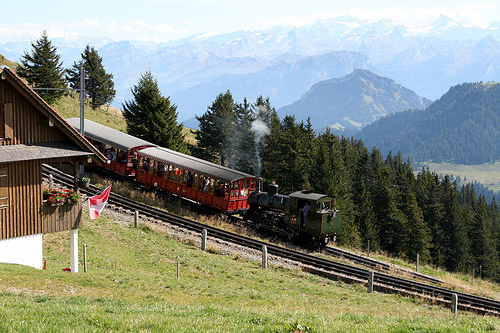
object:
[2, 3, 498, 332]
landscape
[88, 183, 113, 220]
flag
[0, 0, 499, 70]
mountains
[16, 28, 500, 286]
trees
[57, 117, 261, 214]
train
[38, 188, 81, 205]
flowers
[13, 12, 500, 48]
snow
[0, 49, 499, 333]
hill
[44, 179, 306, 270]
rocks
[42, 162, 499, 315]
train tracks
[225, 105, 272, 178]
steam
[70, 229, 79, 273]
post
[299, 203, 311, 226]
conductor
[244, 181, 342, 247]
engine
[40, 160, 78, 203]
window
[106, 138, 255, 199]
passengers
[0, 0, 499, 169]
distance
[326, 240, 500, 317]
empty section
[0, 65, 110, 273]
house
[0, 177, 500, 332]
green area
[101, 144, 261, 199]
windows